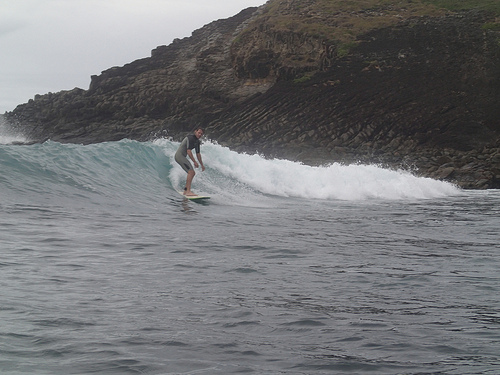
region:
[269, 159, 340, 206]
white spray from wave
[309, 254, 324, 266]
water is dark gray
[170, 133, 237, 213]
man is riding surfboard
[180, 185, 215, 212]
surfboard is white and gray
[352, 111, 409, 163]
rocks on shore are black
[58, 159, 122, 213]
water is blue green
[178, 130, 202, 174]
man is slightly bent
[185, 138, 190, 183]
man is wearing gray suit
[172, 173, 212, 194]
surfboard at bottom of wave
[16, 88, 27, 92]
sky is gray and damp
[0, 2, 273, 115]
grey overcast sky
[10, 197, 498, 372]
dark grey somewhat rough water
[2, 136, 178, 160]
crest of a good surf wave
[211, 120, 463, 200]
water splashing against the rocky shore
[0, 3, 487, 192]
high rocky ridge protrudes into water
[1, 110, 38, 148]
spray from wave just hitting ridge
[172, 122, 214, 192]
man in two tone grey wet suit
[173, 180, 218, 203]
white surf board in use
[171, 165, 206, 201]
man wears a leg strap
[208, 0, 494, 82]
sparse grass on ridge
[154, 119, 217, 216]
The man is on a surfboard.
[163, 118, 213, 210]
The man is wearing a wetsuit.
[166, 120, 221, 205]
The man is barefoot.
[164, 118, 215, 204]
The wetsuit has sleeves.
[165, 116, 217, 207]
The wetsuit sleeves are short.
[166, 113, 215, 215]
The wetsuit is black and gray.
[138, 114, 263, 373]
The surfboard is in the water.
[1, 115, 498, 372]
The water is choppy.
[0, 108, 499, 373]
The water is splashing.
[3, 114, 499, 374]
The water is buoyant.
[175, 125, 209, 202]
man riding on a surfboard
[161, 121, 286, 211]
surfer riding a wave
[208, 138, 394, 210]
white foam from cresting wave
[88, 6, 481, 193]
seaside rock cliff face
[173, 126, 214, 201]
surfer wearing grey and black wetsuit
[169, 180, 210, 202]
man's feet on a surfboard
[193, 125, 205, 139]
head of a surfer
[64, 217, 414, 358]
greenish grey ocean water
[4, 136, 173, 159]
crest of a wave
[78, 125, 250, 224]
ocean wave with surfer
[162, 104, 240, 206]
man surfing in the ocean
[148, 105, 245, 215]
man on a white surfboard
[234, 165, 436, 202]
white foam of crashing wave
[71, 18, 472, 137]
rocky mountain behind surfer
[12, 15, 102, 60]
sky covered with light grey clouds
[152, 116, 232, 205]
man barefoot on surfboard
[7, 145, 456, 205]
long wave to surf on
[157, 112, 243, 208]
man wearing a grey and black wet suit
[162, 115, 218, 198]
man with short brown hair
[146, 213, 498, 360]
calm ocean water before wave